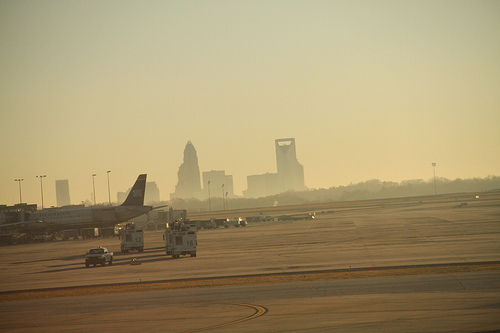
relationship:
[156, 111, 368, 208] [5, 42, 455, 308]
city in background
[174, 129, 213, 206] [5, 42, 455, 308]
building in distance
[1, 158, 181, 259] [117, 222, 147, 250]
plane and vehicle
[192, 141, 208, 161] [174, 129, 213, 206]
edge of building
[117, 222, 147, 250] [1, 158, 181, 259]
vehicle in front of plane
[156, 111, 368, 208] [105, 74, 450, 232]
city in distance